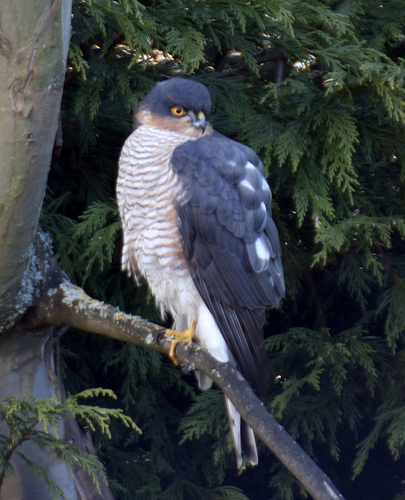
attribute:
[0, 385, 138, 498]
green branch — is green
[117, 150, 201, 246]
breast — is ruffled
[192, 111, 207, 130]
beak — is curved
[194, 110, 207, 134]
beak — is gray, is white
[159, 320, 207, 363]
foot — yellow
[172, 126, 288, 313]
wing — grey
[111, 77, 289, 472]
bird — is gray, is white, grey and white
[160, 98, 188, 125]
eye — is yellow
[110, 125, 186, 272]
chest — is white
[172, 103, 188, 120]
eye — is small